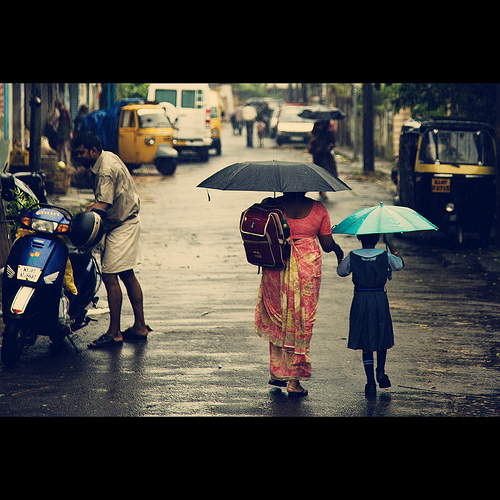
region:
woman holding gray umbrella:
[200, 140, 365, 190]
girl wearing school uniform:
[334, 250, 414, 412]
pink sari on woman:
[243, 231, 327, 391]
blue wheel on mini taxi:
[145, 135, 187, 181]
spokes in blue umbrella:
[367, 193, 389, 248]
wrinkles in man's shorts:
[99, 226, 142, 276]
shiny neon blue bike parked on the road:
[1, 183, 117, 332]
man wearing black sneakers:
[90, 308, 185, 360]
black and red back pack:
[213, 191, 303, 292]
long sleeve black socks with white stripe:
[356, 346, 398, 376]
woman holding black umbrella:
[196, 153, 355, 394]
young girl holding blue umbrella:
[329, 200, 440, 398]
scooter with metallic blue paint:
[8, 192, 110, 372]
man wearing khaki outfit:
[71, 130, 157, 352]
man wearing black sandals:
[71, 131, 156, 351]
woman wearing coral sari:
[208, 157, 343, 403]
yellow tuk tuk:
[76, 100, 183, 182]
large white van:
[141, 85, 226, 152]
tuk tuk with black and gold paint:
[382, 113, 496, 238]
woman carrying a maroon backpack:
[205, 147, 345, 399]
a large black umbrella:
[191, 155, 347, 195]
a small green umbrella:
[332, 200, 438, 236]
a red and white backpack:
[233, 203, 293, 270]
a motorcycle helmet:
[70, 204, 104, 246]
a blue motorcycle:
[1, 201, 103, 339]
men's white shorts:
[99, 215, 143, 277]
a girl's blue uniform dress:
[348, 247, 394, 347]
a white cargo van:
[145, 80, 210, 160]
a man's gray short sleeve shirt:
[91, 150, 137, 222]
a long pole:
[357, 82, 380, 173]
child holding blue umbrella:
[337, 200, 433, 312]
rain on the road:
[131, 318, 229, 453]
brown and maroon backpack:
[213, 206, 290, 291]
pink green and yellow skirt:
[258, 263, 324, 380]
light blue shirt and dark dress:
[340, 245, 418, 360]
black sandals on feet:
[77, 320, 157, 376]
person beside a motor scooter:
[5, 140, 149, 351]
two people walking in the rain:
[199, 152, 449, 377]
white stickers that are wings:
[0, 262, 65, 304]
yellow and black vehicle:
[377, 113, 488, 235]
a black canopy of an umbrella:
[196, 161, 350, 191]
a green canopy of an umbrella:
[331, 201, 437, 233]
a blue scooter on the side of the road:
[3, 203, 101, 366]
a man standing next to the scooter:
[69, 130, 148, 350]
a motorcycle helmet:
[68, 209, 104, 251]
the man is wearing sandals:
[87, 334, 124, 350]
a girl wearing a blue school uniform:
[348, 251, 395, 351]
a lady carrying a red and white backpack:
[239, 203, 292, 271]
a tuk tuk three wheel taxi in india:
[395, 117, 499, 246]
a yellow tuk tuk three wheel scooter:
[76, 100, 177, 176]